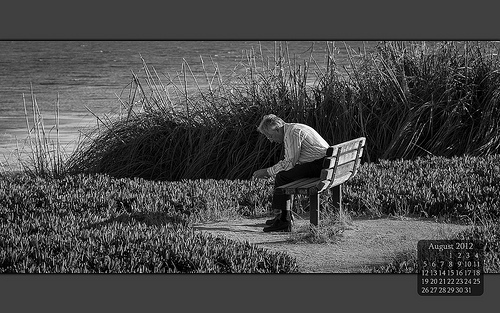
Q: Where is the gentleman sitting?
A: On the bench.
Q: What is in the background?
A: Calm waters.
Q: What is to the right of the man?
A: Tall grass.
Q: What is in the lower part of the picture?
A: Calendar.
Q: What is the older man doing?
A: Sitting down.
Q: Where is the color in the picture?
A: No where, it's black and white.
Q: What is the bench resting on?
A: Slab of concrete.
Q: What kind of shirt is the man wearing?
A: Striped.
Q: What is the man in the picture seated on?
A: A bench.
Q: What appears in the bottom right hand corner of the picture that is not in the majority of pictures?
A: A calendar.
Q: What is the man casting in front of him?
A: A shadow.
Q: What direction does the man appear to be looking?
A: Down.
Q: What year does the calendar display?
A: 2012.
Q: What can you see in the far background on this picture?
A: Water.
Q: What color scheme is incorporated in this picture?
A: Black and White.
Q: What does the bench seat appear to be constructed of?
A: Wood.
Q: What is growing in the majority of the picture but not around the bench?
A: Grass.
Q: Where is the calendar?
A: Corner.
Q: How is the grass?
A: Cut.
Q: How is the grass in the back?
A: Tall.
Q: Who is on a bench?
A: An older man in black pants and a striped, button-down shirt.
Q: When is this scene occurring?
A: In August.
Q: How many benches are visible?
A: One.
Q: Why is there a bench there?
A: For people to rest and look at the water.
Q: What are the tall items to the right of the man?
A: Rushes.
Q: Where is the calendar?
A: In the right, bottom, corner.